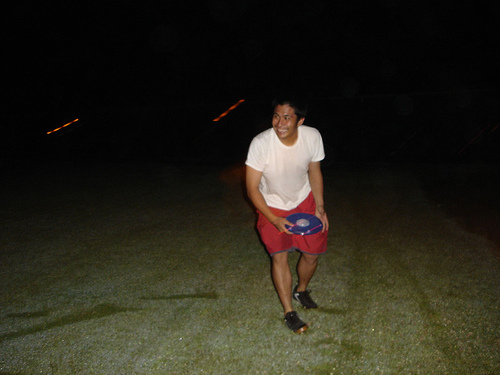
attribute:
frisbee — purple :
[282, 210, 320, 233]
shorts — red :
[261, 213, 332, 253]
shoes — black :
[277, 290, 323, 329]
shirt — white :
[247, 126, 327, 209]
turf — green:
[340, 332, 396, 356]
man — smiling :
[253, 101, 340, 365]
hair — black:
[263, 90, 307, 123]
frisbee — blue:
[275, 203, 340, 285]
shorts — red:
[226, 190, 340, 275]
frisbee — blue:
[252, 188, 342, 248]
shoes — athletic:
[222, 232, 361, 363]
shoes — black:
[267, 277, 373, 367]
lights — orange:
[33, 82, 125, 200]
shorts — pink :
[232, 168, 369, 276]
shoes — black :
[245, 257, 365, 373]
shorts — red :
[224, 180, 457, 304]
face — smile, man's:
[252, 98, 305, 138]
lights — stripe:
[37, 112, 90, 135]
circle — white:
[291, 215, 313, 226]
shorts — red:
[260, 199, 327, 252]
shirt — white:
[245, 130, 321, 210]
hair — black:
[265, 90, 300, 110]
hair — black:
[283, 95, 303, 102]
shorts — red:
[255, 190, 325, 254]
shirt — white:
[252, 133, 319, 205]